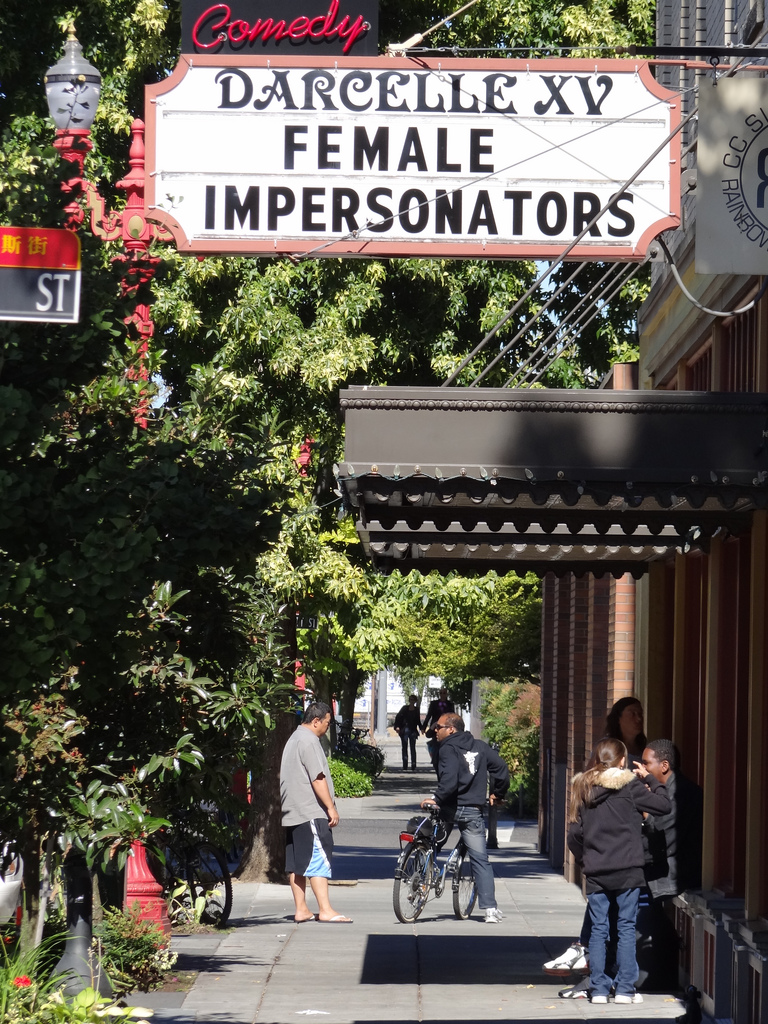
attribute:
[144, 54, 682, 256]
sign — white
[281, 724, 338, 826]
shirt — gray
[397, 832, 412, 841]
reflector light — red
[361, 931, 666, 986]
shadow — rectangle shape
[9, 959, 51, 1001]
flower — small, red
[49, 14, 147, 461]
lamp — red, large, street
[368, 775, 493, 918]
bike — black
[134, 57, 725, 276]
sign — white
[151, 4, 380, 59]
sign — black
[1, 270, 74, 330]
letters — white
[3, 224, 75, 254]
letters — yellow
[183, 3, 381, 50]
letters — red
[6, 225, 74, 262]
sign — red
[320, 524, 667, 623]
letters — black